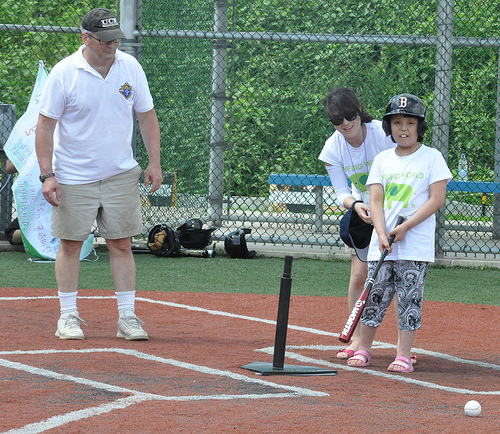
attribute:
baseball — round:
[464, 401, 484, 426]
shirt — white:
[31, 69, 173, 181]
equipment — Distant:
[147, 218, 257, 255]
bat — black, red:
[339, 214, 406, 338]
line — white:
[114, 345, 326, 397]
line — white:
[1, 355, 151, 400]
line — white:
[1, 342, 118, 357]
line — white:
[1, 395, 153, 431]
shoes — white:
[39, 301, 159, 347]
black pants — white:
[358, 257, 426, 332]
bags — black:
[4, 59, 105, 261]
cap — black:
[81, 13, 135, 53]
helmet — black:
[379, 90, 429, 139]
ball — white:
[462, 395, 482, 418]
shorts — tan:
[51, 162, 144, 238]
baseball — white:
[462, 398, 484, 419]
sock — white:
[99, 275, 161, 348]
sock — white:
[50, 277, 95, 345]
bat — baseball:
[324, 209, 414, 349]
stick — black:
[244, 237, 305, 383]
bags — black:
[137, 215, 261, 258]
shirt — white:
[360, 144, 452, 262]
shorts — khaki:
[46, 156, 146, 244]